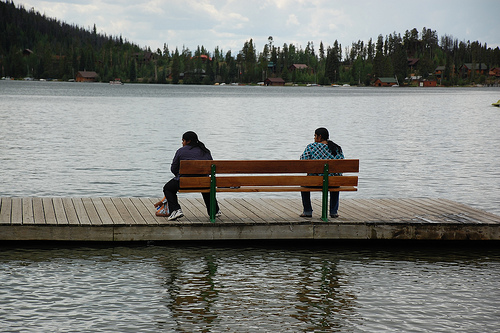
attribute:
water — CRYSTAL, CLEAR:
[2, 77, 483, 331]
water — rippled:
[312, 253, 452, 326]